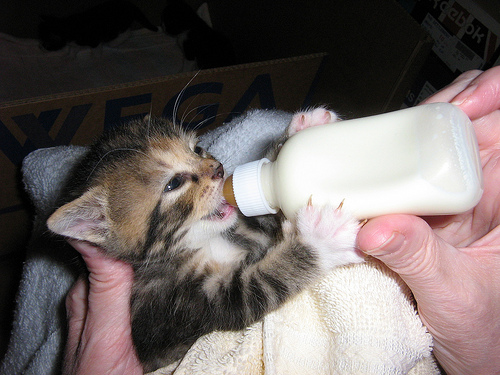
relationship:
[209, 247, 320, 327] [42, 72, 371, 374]
leg of kitten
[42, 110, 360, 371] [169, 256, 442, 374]
kitten in blanket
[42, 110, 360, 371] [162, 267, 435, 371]
kitten in a towel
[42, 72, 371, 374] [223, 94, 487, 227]
kitten feeding from bottle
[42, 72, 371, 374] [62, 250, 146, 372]
kitten on hand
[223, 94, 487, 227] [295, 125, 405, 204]
bottle has milk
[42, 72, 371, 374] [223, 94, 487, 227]
kitten holds bottle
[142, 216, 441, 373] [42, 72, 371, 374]
blanket around kitten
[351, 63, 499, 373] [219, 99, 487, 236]
hand holds bottle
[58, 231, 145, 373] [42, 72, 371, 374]
hand caress kitten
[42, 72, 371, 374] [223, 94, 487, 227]
kitten drink from bottle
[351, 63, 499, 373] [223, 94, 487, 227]
hand holds bottle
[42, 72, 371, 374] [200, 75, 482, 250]
kitten holding bottle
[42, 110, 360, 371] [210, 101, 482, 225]
kitten with bottle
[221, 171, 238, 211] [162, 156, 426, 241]
nipple on bottle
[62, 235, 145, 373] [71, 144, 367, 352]
hand on kitten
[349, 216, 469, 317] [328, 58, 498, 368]
thumb of person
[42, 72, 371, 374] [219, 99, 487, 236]
kitten holding bottle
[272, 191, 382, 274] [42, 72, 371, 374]
paw of kitten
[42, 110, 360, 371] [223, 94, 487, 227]
kitten holding bottle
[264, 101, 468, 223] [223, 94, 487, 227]
milk in a bottle